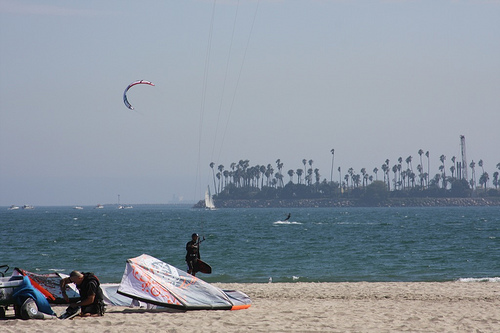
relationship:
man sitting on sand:
[59, 266, 107, 319] [273, 289, 365, 329]